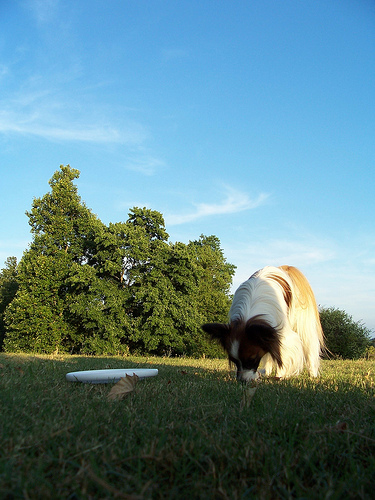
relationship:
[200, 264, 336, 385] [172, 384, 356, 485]
dog in grass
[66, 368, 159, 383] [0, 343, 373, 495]
frisbee on ground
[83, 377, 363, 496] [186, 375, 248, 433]
shadow on ground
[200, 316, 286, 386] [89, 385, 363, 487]
head bent to ground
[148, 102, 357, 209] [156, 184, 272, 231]
sky has cloud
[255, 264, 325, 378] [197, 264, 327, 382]
light shining on dog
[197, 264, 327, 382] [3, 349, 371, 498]
dog sniffing grass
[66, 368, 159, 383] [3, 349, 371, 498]
frisbee in grass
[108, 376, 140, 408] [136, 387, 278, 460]
leaf in grass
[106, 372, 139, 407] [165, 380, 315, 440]
leaf in grass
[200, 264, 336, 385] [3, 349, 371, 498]
dog in grass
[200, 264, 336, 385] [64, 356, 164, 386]
dog playing frisbee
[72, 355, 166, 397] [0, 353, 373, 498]
white frisbee on field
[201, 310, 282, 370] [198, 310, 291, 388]
fur on head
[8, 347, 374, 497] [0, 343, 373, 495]
shadow on ground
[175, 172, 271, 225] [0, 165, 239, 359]
clouds are above trees